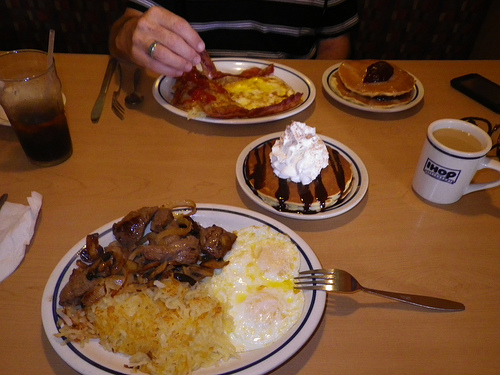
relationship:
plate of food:
[33, 202, 342, 372] [83, 213, 299, 366]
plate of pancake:
[233, 131, 369, 219] [245, 122, 355, 214]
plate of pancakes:
[321, 57, 426, 119] [339, 58, 417, 97]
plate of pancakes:
[321, 57, 426, 119] [329, 70, 414, 107]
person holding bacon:
[94, 5, 372, 68] [188, 41, 276, 85]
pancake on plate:
[227, 122, 370, 227] [228, 124, 375, 221]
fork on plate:
[292, 267, 467, 317] [33, 202, 342, 372]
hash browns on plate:
[60, 272, 258, 373] [33, 202, 342, 372]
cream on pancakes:
[272, 127, 344, 188] [228, 131, 389, 195]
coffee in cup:
[430, 127, 488, 154] [411, 114, 498, 208]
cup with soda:
[0, 45, 74, 168] [15, 107, 76, 162]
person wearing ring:
[94, 5, 372, 68] [138, 27, 168, 67]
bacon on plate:
[173, 72, 230, 116] [150, 49, 315, 134]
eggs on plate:
[216, 64, 294, 101] [150, 49, 315, 134]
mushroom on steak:
[218, 230, 231, 249] [56, 223, 236, 307]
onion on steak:
[156, 214, 192, 245] [56, 223, 236, 307]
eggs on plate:
[164, 211, 374, 350] [33, 202, 342, 372]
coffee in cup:
[430, 127, 488, 154] [399, 114, 499, 225]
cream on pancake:
[268, 121, 329, 184] [227, 122, 370, 227]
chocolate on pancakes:
[326, 146, 351, 201] [243, 135, 354, 211]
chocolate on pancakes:
[313, 177, 328, 212] [243, 135, 354, 211]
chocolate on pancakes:
[294, 181, 312, 212] [243, 135, 354, 211]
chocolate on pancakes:
[274, 177, 290, 212] [243, 135, 354, 211]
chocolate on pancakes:
[251, 145, 265, 195] [243, 135, 354, 211]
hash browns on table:
[60, 272, 258, 373] [6, 47, 498, 368]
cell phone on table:
[446, 62, 498, 122] [6, 47, 498, 368]